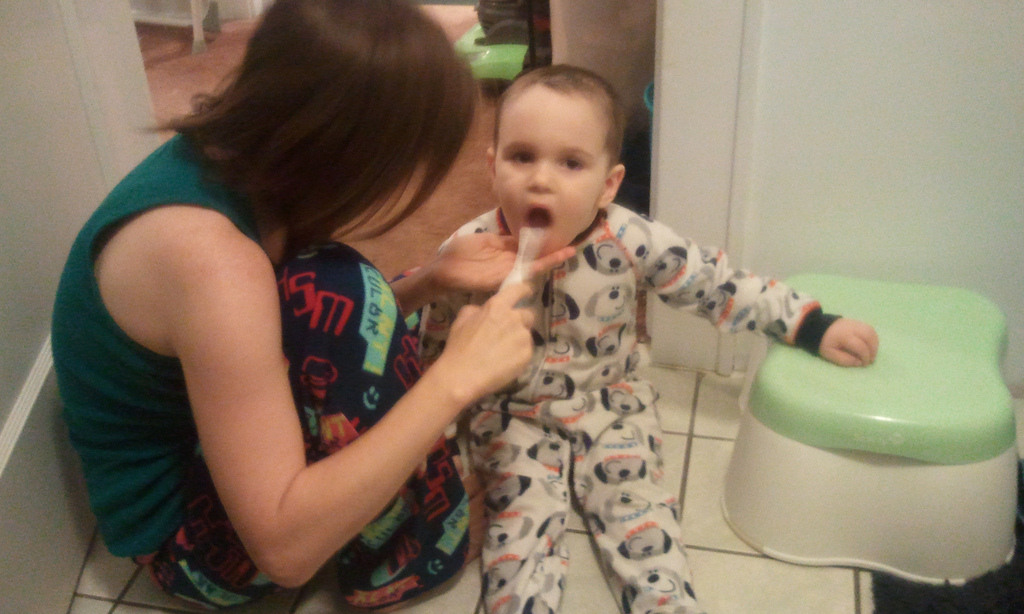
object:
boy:
[399, 59, 884, 614]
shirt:
[47, 136, 266, 558]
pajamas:
[424, 201, 837, 614]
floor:
[72, 357, 992, 614]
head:
[485, 61, 627, 261]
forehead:
[496, 85, 606, 153]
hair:
[492, 63, 627, 178]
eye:
[509, 150, 537, 165]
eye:
[558, 157, 585, 172]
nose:
[525, 158, 557, 195]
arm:
[633, 213, 880, 372]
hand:
[814, 316, 879, 368]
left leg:
[569, 400, 704, 614]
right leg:
[473, 404, 571, 612]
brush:
[498, 223, 548, 288]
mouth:
[521, 203, 556, 232]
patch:
[358, 263, 399, 378]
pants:
[139, 236, 479, 613]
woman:
[50, 0, 573, 614]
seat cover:
[744, 266, 1017, 467]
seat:
[723, 268, 1022, 590]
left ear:
[595, 163, 625, 208]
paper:
[452, 22, 531, 82]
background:
[128, 0, 656, 275]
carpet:
[871, 452, 1024, 613]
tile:
[49, 338, 876, 614]